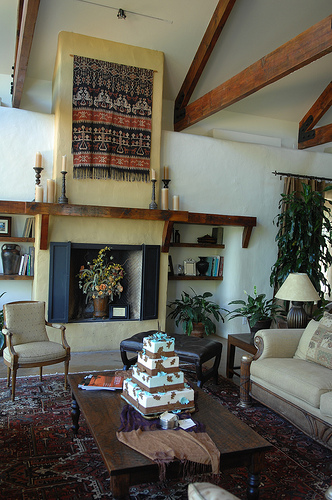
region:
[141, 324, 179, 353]
Section of a big cake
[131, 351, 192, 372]
Section of a big cake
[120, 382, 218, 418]
Section of a big cake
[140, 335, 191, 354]
Section of a big cake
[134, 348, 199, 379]
Section of a big cake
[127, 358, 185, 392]
Section of a big cake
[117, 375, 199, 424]
Section of a big cake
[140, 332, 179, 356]
Section of a big cake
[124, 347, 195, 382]
Section of a big cake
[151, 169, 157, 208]
A candle on a shelf.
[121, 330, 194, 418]
A tall cake on a table.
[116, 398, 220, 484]
A blanket on a table.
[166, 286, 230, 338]
A plant on a table.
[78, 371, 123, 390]
A book on a table.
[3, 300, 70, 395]
A chair that is on a rug.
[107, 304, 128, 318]
A framed paper on a shelf.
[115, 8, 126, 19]
A light on the ceiling.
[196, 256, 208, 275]
A vase on the shelf.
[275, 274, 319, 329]
A lamp on the table.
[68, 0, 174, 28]
Single ceiling mounted track light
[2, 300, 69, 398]
Wood framed Queen Anne style armed chair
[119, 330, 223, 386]
Black cushioned bench ottoman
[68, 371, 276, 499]
Brown wood stained coffee table with turned legs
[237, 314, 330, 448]
Queen Anne style rolled arm tan and wood sofa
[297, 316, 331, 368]
Square throw pillows, one tan and one with tan pattern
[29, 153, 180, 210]
Black candlestick holders with tan candles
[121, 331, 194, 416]
Four graduated layer brown and white frosted cake with blue accents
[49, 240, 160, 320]
Black doors on fire place with floral arrangement in firebox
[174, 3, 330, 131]
Open framed wood beam ceiling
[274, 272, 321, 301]
the shade on the lamp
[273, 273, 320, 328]
the lamp on the end table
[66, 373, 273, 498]
the wooden coffee table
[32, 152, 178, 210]
the candles on the mantle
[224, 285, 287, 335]
the plant on the end table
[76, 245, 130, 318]
the potted flowers in the fireplace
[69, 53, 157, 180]
the fabric hanging on the wall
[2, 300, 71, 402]
the empty arm chair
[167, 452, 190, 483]
part of a cloth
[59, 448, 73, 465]
part of a carpet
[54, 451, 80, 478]
part of a floor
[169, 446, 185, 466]
part of a fiold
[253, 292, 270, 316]
green leaves on the plant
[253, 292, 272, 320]
green leaves on the plant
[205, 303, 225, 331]
green leaves on the plant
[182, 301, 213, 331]
green leaves on the plant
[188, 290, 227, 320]
green leaves on the plant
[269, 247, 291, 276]
green leaves on the plant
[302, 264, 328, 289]
green leaves on the plant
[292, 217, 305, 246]
green leaves on the plant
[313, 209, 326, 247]
green leaves on the plant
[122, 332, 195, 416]
Tall brown and white cake with blue leaves.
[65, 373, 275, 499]
A long brown coffee table.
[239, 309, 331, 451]
A tan and cream colored couch.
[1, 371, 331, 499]
A large mostly red area rug.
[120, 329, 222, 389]
A black ottoman on an area rug.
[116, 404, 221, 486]
Brown and purple scarf on the table.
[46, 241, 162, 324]
Fireplace with flowers inside it.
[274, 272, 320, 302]
A cream colored lamp shade.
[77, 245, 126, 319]
A bouquet of flowers in a brown vase.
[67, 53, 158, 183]
fringed fabric hanging wall art